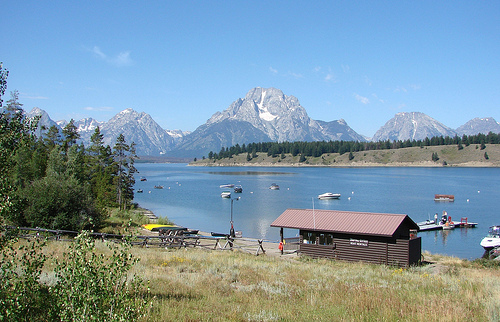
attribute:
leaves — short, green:
[0, 217, 158, 321]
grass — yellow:
[39, 241, 496, 321]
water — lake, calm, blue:
[133, 160, 499, 255]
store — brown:
[276, 203, 423, 270]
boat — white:
[134, 177, 499, 252]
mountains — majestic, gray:
[1, 86, 500, 152]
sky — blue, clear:
[4, 4, 498, 132]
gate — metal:
[17, 222, 298, 254]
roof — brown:
[268, 201, 423, 241]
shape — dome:
[374, 111, 454, 145]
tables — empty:
[145, 223, 210, 255]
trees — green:
[35, 118, 144, 206]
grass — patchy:
[189, 230, 287, 276]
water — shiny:
[251, 166, 273, 239]